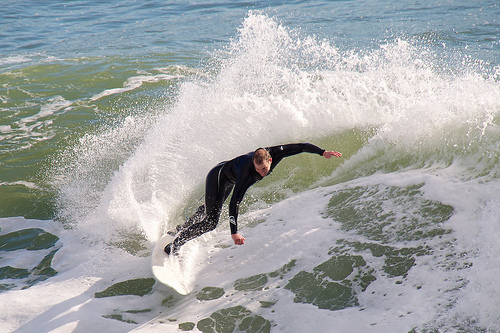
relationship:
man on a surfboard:
[164, 145, 342, 261] [147, 201, 220, 298]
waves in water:
[2, 49, 210, 206] [3, 3, 498, 332]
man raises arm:
[164, 145, 342, 261] [278, 141, 343, 160]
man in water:
[164, 145, 342, 261] [3, 3, 498, 332]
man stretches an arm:
[164, 145, 342, 261] [278, 141, 343, 160]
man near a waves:
[164, 145, 342, 261] [2, 49, 210, 206]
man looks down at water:
[164, 145, 342, 261] [3, 3, 498, 332]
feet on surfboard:
[164, 224, 190, 256] [147, 201, 220, 298]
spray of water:
[30, 9, 500, 241] [3, 3, 498, 332]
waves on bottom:
[2, 49, 210, 206] [1, 81, 149, 131]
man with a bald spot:
[164, 145, 342, 261] [255, 148, 269, 159]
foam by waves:
[1, 165, 499, 327] [2, 49, 210, 206]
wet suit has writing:
[166, 144, 325, 248] [230, 212, 238, 229]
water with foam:
[3, 3, 498, 332] [1, 165, 499, 327]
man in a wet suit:
[164, 145, 342, 261] [166, 144, 325, 248]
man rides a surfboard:
[164, 145, 342, 261] [147, 201, 220, 298]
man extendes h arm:
[164, 145, 342, 261] [226, 178, 243, 245]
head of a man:
[251, 146, 273, 179] [164, 145, 342, 261]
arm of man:
[226, 178, 243, 245] [164, 145, 342, 261]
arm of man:
[278, 141, 343, 160] [164, 145, 342, 261]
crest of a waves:
[6, 54, 180, 84] [2, 49, 210, 206]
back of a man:
[215, 150, 261, 171] [164, 145, 342, 261]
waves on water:
[2, 49, 210, 206] [3, 3, 498, 332]